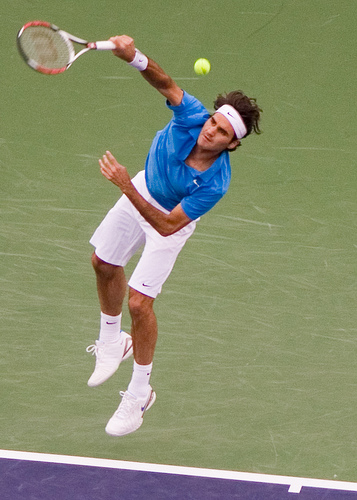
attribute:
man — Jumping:
[68, 34, 259, 435]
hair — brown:
[220, 86, 282, 141]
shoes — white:
[81, 325, 162, 439]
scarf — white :
[213, 103, 251, 142]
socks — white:
[98, 312, 125, 335]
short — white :
[90, 170, 202, 300]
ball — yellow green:
[181, 48, 261, 111]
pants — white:
[85, 167, 201, 302]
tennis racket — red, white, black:
[15, 19, 120, 73]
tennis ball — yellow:
[186, 45, 224, 82]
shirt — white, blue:
[101, 54, 279, 269]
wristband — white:
[125, 48, 147, 71]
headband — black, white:
[220, 104, 250, 138]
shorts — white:
[84, 163, 200, 305]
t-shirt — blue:
[145, 90, 231, 220]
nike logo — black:
[225, 110, 234, 118]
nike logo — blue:
[137, 394, 151, 414]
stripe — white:
[0, 449, 357, 494]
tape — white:
[95, 36, 117, 48]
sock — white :
[122, 360, 157, 396]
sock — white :
[95, 308, 122, 345]